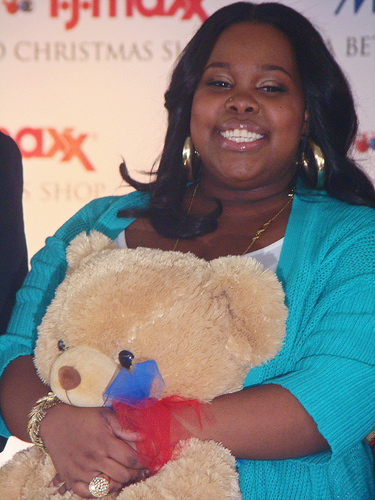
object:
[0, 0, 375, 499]
woman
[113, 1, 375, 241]
hair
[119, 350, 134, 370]
eye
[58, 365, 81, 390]
nose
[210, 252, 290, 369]
ear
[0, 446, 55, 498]
arm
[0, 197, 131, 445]
arm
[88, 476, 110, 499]
ring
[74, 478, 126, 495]
finger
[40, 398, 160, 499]
hand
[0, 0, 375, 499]
lady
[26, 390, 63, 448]
bracelet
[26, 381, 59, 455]
wrist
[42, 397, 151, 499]
lap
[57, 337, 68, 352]
eye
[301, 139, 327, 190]
earrings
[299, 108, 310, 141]
ear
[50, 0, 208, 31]
advertisement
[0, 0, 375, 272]
wall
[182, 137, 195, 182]
earring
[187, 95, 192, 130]
ear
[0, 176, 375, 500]
jacket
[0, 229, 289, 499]
bear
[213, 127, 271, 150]
teeth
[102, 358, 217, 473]
net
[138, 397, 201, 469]
wrist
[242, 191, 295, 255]
chain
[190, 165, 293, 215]
neck